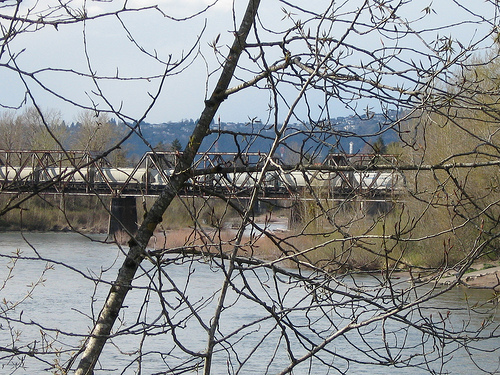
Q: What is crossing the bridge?
A: Train.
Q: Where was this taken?
A: Beside a river.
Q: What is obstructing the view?
A: Branches.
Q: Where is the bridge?
A: Center frame.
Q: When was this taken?
A: Day time.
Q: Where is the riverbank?
A: Lower right quadrant.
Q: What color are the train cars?
A: White.